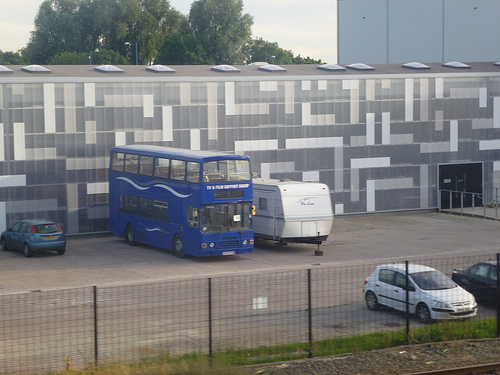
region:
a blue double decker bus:
[89, 120, 268, 288]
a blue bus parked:
[42, 75, 282, 285]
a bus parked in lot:
[64, 97, 322, 285]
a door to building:
[426, 142, 499, 214]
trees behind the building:
[32, 0, 328, 89]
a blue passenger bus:
[105, 122, 306, 288]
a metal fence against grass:
[99, 250, 477, 360]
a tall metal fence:
[111, 267, 448, 374]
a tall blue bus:
[82, 111, 262, 271]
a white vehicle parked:
[352, 222, 485, 357]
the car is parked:
[342, 247, 486, 337]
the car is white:
[340, 248, 482, 331]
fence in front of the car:
[346, 238, 491, 345]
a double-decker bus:
[103, 131, 259, 282]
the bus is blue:
[93, 115, 275, 312]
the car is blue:
[8, 212, 105, 269]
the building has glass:
[38, 81, 410, 214]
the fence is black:
[134, 280, 317, 357]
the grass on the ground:
[238, 333, 371, 359]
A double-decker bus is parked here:
[104, 132, 269, 266]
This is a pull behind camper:
[254, 165, 339, 259]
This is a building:
[4, 59, 494, 231]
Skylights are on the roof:
[1, 54, 476, 76]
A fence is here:
[4, 257, 434, 360]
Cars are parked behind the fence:
[359, 242, 499, 331]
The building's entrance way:
[432, 157, 489, 218]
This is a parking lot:
[3, 212, 498, 336]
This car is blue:
[2, 215, 74, 261]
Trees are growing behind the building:
[29, 2, 296, 91]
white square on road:
[237, 290, 287, 316]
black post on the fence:
[197, 257, 228, 370]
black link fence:
[107, 301, 190, 351]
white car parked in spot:
[354, 244, 479, 327]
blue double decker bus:
[108, 137, 276, 254]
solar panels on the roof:
[95, 53, 320, 77]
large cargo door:
[433, 143, 498, 221]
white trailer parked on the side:
[253, 166, 339, 242]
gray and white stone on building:
[278, 92, 394, 144]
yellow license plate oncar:
[30, 223, 85, 246]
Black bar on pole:
[195, 276, 225, 366]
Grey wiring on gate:
[104, 293, 205, 344]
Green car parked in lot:
[0, 196, 75, 273]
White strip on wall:
[33, 81, 68, 141]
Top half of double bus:
[108, 146, 260, 203]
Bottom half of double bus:
[102, 189, 263, 263]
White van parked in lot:
[256, 158, 338, 258]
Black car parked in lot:
[451, 245, 498, 307]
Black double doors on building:
[429, 151, 491, 213]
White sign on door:
[439, 176, 458, 186]